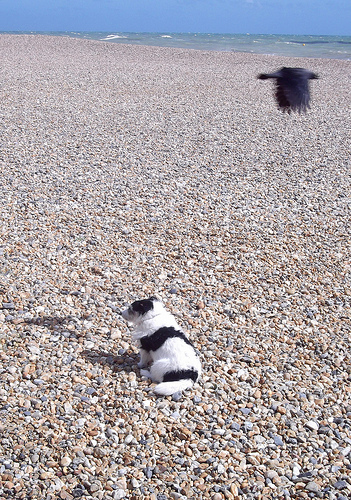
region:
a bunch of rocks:
[82, 176, 180, 262]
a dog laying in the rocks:
[100, 281, 204, 415]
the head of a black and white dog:
[116, 287, 157, 323]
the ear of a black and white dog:
[138, 297, 160, 315]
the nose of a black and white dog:
[116, 304, 122, 319]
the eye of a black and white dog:
[122, 300, 137, 317]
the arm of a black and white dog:
[125, 330, 153, 368]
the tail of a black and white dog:
[162, 369, 205, 414]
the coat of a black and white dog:
[145, 301, 171, 329]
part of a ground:
[226, 344, 257, 375]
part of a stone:
[191, 462, 202, 479]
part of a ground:
[166, 433, 190, 477]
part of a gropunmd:
[171, 446, 201, 485]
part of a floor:
[191, 427, 212, 470]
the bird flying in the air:
[243, 53, 325, 116]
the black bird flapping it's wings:
[249, 61, 326, 118]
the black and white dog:
[102, 287, 216, 400]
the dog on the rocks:
[116, 292, 205, 398]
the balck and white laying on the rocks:
[115, 293, 203, 395]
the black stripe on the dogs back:
[138, 324, 192, 352]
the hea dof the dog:
[116, 292, 164, 322]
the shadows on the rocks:
[20, 313, 124, 373]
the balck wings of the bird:
[271, 77, 317, 115]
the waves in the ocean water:
[1, 25, 348, 57]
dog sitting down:
[110, 297, 216, 399]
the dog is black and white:
[111, 294, 211, 398]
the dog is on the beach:
[114, 298, 216, 398]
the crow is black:
[254, 58, 327, 117]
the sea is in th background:
[127, 28, 326, 53]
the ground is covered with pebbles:
[3, 414, 349, 498]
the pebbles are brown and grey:
[1, 414, 350, 497]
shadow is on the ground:
[28, 312, 89, 340]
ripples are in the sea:
[104, 27, 176, 46]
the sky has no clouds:
[3, 1, 345, 34]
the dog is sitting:
[118, 295, 200, 395]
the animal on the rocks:
[118, 294, 198, 395]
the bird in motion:
[256, 66, 321, 114]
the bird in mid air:
[256, 66, 319, 113]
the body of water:
[0, 30, 349, 60]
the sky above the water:
[0, 0, 349, 36]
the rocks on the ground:
[0, 33, 349, 498]